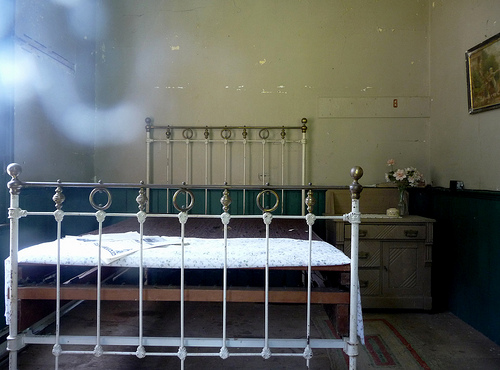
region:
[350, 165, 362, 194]
A brass bed knob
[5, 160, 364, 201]
Two brass bed knobs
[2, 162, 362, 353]
The foot of a metal bed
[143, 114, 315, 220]
The headboard of a metal bed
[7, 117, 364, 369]
A white iron bed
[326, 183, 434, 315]
A wooden bed stand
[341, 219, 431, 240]
Top drawer of a bed stand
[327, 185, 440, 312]
A bed side table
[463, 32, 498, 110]
A painting on the wall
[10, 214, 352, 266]
A bed matress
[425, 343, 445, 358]
part of a carpet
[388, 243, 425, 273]
part of a board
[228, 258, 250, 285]
edge of a sheet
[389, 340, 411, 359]
part of a carpet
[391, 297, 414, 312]
edge of a board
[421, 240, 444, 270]
edge of a board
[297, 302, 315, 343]
part of a metal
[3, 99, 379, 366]
an old white bed frame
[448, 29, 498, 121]
a framed painting decorating the room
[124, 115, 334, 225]
a metal headboard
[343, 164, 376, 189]
a brass bedpost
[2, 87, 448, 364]
an iron-framed bed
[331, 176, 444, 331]
a small wooden bedside dresser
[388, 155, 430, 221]
a small bottle with flowers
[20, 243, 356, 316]
a wooden boxspring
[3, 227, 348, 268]
a white sheet draped on the bed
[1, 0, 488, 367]
an old bedroom with a very little furniture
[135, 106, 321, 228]
Headboard of white bed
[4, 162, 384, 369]
Footboard of white bed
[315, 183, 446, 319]
Brown wooden end table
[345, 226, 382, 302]
End table wooden drawers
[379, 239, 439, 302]
End table wooden cabinet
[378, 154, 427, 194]
White flowers in vase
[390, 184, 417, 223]
Vase holding white flowers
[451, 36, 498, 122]
Picture on bedroom wall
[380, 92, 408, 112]
Number 8 on bedroom wall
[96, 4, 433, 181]
Painted white bedroom wall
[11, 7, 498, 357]
A bed room with bed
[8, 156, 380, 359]
A metal bed with wood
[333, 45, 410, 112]
A white color wall tiles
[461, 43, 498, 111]
A photo frame hanging in the wall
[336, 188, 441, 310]
A small size cupboard near the bed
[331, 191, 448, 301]
Wooden cupboard near the wall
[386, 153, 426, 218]
Flower wash kept above the cupboard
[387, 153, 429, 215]
Flower wash with flowers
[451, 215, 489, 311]
Green color wall tiles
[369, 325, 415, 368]
Floor mate